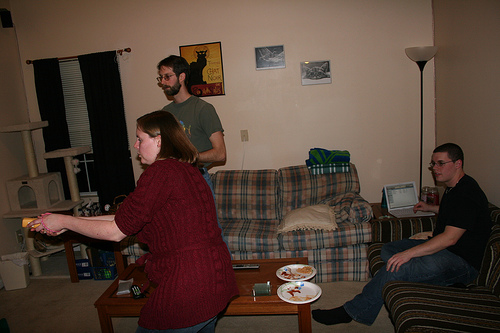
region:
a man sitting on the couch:
[320, 140, 497, 307]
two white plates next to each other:
[276, 259, 322, 309]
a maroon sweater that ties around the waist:
[115, 154, 248, 321]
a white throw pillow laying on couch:
[280, 185, 341, 246]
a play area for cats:
[7, 118, 97, 293]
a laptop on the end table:
[382, 173, 437, 230]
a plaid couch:
[119, 153, 384, 288]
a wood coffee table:
[88, 248, 323, 331]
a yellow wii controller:
[19, 201, 74, 243]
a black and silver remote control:
[230, 259, 262, 270]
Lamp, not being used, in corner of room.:
[405, 46, 437, 200]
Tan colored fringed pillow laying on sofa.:
[280, 204, 337, 231]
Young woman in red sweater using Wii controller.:
[20, 106, 243, 330]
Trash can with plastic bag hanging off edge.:
[0, 250, 35, 290]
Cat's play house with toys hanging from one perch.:
[1, 113, 93, 278]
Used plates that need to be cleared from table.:
[275, 259, 322, 306]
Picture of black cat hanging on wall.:
[178, 39, 229, 102]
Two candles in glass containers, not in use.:
[417, 182, 444, 208]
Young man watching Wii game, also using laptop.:
[312, 141, 482, 326]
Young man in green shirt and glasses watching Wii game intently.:
[155, 55, 227, 168]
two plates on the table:
[74, 248, 337, 328]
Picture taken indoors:
[42, 36, 489, 243]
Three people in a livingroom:
[36, 50, 452, 330]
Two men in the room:
[140, 52, 456, 240]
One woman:
[76, 123, 211, 295]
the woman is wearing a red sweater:
[50, 160, 257, 325]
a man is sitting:
[374, 98, 498, 280]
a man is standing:
[155, 43, 244, 182]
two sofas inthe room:
[245, 162, 475, 324]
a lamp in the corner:
[388, 37, 461, 218]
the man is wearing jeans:
[367, 247, 434, 284]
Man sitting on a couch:
[313, 139, 490, 331]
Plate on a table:
[274, 261, 319, 281]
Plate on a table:
[276, 279, 324, 308]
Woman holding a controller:
[20, 106, 241, 331]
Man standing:
[143, 47, 234, 202]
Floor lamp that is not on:
[398, 38, 443, 206]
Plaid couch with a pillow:
[196, 150, 381, 278]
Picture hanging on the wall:
[252, 40, 287, 70]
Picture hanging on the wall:
[298, 58, 333, 84]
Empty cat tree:
[1, 110, 91, 290]